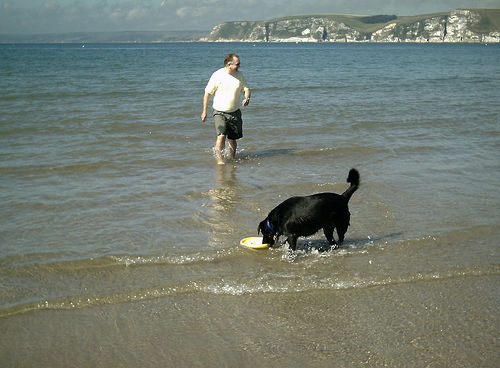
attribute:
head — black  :
[251, 212, 278, 249]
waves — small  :
[3, 217, 498, 322]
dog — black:
[260, 173, 372, 264]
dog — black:
[256, 168, 365, 255]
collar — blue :
[262, 215, 274, 232]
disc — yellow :
[240, 235, 267, 248]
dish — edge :
[239, 233, 270, 253]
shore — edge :
[2, 137, 496, 365]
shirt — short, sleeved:
[207, 64, 252, 111]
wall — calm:
[52, 52, 185, 166]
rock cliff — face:
[233, 20, 457, 50]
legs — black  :
[322, 227, 334, 247]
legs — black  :
[336, 224, 348, 244]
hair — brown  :
[226, 41, 241, 70]